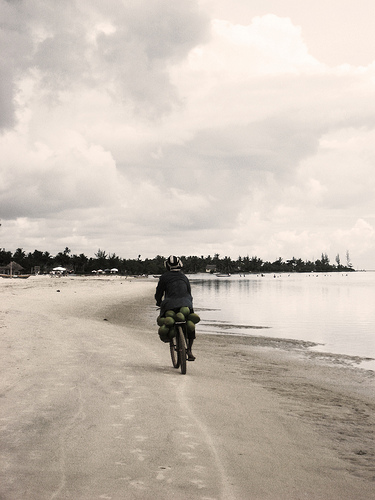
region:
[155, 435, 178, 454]
the sand is gray white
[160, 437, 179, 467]
the sand is gray white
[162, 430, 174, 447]
the sand is gray white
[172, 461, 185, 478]
the sand is gray white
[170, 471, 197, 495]
the sand is gray white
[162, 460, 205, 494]
the sand is gray white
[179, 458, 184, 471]
the sand is gray white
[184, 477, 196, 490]
the sand is gray white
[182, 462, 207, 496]
the sand is gray white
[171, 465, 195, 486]
the sand is gray white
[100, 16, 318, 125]
this is the sky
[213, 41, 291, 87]
these are the clouds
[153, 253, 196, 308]
this is a man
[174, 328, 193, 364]
this is a bicycle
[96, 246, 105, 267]
this is a tree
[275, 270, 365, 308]
this is a water body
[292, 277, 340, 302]
the water is calm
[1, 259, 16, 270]
this is a house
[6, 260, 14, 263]
this is the roof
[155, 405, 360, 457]
this is the beach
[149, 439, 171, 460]
THE SAND IS GRAY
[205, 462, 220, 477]
THE SAND IS GRAY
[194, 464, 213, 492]
THE SAND IS GRAY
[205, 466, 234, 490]
THE SAND IS GRAY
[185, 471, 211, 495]
THE SAND IS GRAY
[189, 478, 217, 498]
THE SAND IS GRAY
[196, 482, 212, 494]
THE SAND IS GRAY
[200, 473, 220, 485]
THE SAND IS GRAY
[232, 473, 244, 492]
THE SAND IS GRAY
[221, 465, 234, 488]
THE SAND IS GRAY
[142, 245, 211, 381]
person riding a bike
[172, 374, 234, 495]
long, thin bike track in the sand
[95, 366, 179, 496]
footprints in the sand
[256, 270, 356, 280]
people in the water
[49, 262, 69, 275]
white umbrella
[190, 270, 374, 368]
body of water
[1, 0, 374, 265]
sky covered in clouds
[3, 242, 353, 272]
long row of dark trees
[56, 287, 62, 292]
a small black object laying in the sand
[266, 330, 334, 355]
sand mixing with the water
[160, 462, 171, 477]
black spot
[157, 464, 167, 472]
black spot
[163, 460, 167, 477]
black spot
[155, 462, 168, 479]
black spot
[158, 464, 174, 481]
black spot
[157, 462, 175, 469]
black spot